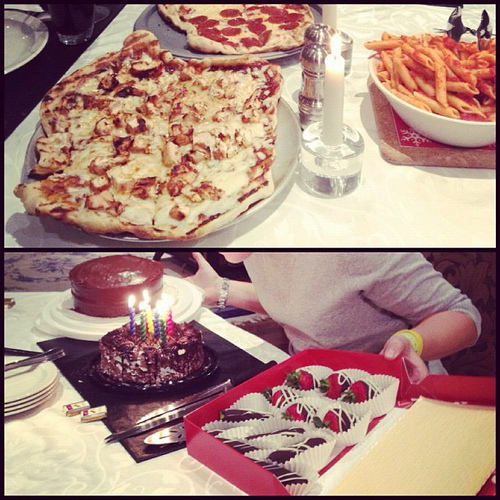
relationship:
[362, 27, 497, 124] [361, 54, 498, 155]
pasta in bowl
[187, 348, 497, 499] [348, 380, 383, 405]
red box full of strawberries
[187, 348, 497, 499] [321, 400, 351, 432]
red box full of strawberries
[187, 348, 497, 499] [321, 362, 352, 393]
red box full of strawberries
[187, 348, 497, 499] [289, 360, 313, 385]
red box full of strawberries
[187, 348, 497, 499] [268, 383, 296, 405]
red box full of strawberries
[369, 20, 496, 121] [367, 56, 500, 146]
pasta in bowl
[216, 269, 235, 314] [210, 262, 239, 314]
bracelet on wrist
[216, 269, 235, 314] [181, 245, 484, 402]
bracelet on woman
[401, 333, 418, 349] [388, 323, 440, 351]
bracelet on wrist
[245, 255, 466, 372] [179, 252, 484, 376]
shirt on person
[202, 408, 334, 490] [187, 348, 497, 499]
cupcakes in red box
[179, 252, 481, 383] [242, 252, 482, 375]
person wearing shirt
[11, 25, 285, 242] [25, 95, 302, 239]
pizza on plate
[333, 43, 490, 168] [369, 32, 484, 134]
bowl of pasta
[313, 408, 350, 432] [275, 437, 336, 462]
strawberries in paper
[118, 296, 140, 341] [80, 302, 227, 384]
candle on cake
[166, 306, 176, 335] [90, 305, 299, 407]
candle on cake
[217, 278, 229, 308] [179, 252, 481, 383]
bracelet on person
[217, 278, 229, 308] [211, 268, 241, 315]
bracelet on wrist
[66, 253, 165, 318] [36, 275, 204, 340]
cake on platter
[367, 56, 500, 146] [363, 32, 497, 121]
bowl surrounding fries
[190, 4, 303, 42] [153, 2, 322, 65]
toppings on pizza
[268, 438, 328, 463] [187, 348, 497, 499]
cupcakes in red box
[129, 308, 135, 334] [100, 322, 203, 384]
candle on cake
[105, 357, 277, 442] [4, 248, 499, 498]
knife on table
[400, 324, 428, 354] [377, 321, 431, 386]
wristband worn on hand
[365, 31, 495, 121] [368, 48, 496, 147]
noodles in bowl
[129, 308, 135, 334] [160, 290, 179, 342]
candle next to candle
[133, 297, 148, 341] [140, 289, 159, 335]
candle next to candle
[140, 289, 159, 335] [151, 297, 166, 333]
candle next to candle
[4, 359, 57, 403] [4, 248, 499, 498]
plate on table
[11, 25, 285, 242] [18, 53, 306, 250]
pizza on plate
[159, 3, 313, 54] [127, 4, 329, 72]
pepperoni pizza on plate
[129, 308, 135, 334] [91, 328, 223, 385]
candle on cake